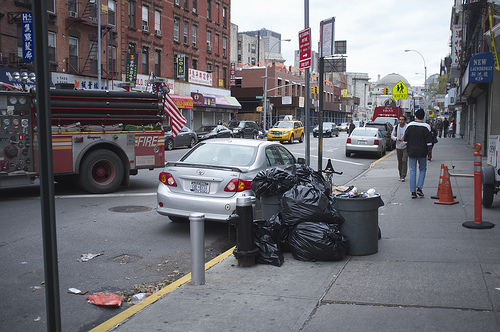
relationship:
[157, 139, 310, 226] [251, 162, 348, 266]
sedan near trash pile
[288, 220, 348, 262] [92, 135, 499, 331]
bag on sidewalk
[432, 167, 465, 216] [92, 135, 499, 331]
cones on sidewalk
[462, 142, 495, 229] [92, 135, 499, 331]
safety post on sidewalk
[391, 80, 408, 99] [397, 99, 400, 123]
pedestrian sign on pole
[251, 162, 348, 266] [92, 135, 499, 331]
bags on sidewalk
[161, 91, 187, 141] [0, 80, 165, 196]
flag on firetruck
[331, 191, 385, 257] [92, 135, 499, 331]
garbage can on sidewalk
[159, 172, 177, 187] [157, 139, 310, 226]
tailight on sedan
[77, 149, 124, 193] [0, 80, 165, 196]
tire on firetruck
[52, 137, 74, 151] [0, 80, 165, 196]
stripe on firetruck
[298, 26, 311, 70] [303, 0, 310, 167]
sign on pole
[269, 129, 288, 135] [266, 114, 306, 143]
grill on taxi